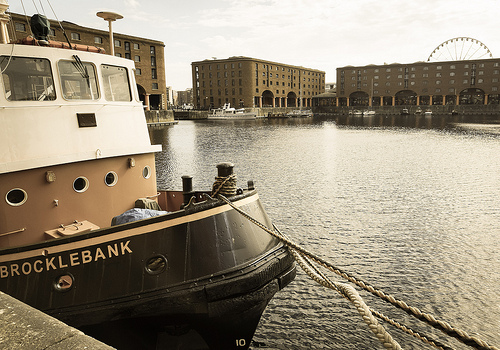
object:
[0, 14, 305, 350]
boat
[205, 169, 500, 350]
rope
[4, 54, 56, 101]
windows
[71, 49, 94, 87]
wiper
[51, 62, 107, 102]
windshield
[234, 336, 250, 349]
number 10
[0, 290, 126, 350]
dock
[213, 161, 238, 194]
post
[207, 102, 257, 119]
boat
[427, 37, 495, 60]
ferris wheel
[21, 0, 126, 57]
rigging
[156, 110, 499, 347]
water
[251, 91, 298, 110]
walking path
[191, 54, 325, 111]
buildings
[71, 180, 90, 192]
windows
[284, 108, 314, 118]
boats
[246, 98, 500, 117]
wall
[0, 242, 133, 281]
name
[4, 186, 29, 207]
porthole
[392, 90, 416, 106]
arches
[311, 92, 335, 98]
awning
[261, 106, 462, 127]
shadow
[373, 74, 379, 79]
windows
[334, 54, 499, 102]
building